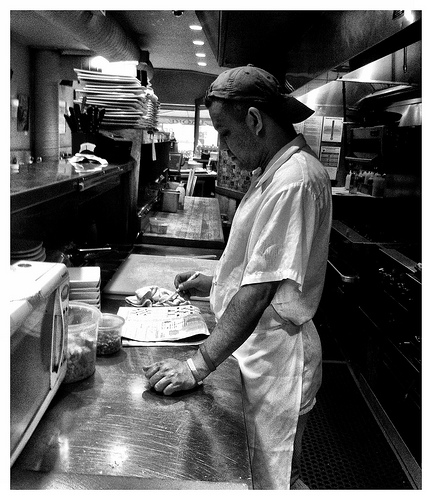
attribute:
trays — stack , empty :
[75, 61, 162, 136]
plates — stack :
[72, 64, 162, 134]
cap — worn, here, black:
[211, 61, 313, 124]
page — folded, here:
[119, 303, 207, 346]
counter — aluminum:
[11, 184, 254, 488]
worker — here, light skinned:
[145, 60, 334, 499]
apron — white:
[218, 181, 298, 488]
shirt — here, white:
[225, 151, 322, 326]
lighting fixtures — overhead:
[189, 20, 211, 76]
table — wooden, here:
[140, 185, 231, 249]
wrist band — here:
[193, 343, 218, 373]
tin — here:
[159, 187, 181, 212]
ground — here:
[239, 316, 421, 492]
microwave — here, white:
[10, 259, 74, 470]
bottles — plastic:
[344, 163, 414, 201]